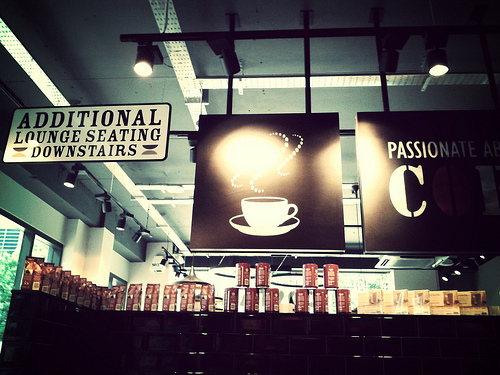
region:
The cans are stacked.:
[218, 252, 366, 321]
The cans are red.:
[219, 252, 351, 317]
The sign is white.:
[2, 104, 169, 168]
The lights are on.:
[51, 169, 78, 193]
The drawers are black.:
[12, 265, 490, 374]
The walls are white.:
[58, 204, 169, 291]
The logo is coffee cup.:
[197, 112, 334, 260]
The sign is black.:
[360, 109, 485, 262]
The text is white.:
[355, 115, 470, 237]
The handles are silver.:
[335, 308, 395, 365]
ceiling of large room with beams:
[25, 10, 466, 95]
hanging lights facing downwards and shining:
[115, 30, 461, 85]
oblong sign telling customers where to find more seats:
[2, 85, 172, 175]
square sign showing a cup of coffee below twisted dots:
[182, 60, 352, 277]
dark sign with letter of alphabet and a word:
[355, 80, 491, 260]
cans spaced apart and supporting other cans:
[217, 260, 349, 311]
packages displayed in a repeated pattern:
[357, 281, 487, 316]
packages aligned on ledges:
[15, 242, 216, 313]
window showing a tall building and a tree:
[1, 215, 26, 317]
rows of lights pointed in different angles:
[63, 175, 183, 275]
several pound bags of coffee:
[6, 230, 226, 316]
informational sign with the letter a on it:
[0, 80, 188, 187]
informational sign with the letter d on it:
[0, 86, 199, 173]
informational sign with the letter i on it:
[0, 88, 196, 182]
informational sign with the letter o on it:
[0, 79, 192, 176]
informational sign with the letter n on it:
[0, 81, 206, 196]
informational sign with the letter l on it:
[1, 86, 187, 179]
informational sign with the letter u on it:
[3, 77, 188, 176]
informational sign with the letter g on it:
[0, 78, 182, 220]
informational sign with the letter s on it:
[7, 51, 192, 175]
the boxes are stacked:
[219, 261, 281, 312]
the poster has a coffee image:
[191, 112, 338, 247]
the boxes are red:
[225, 262, 348, 309]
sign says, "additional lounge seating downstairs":
[3, 107, 172, 162]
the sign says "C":
[366, 110, 488, 252]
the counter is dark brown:
[1, 288, 499, 371]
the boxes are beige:
[358, 288, 488, 314]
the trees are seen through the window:
[0, 210, 25, 336]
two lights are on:
[133, 60, 449, 76]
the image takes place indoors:
[0, 0, 499, 372]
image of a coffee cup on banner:
[224, 187, 313, 241]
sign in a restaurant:
[0, 98, 178, 172]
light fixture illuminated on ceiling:
[124, 38, 173, 79]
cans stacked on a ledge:
[214, 254, 292, 319]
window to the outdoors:
[0, 219, 21, 293]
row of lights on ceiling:
[65, 162, 162, 252]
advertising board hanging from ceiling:
[349, 101, 494, 263]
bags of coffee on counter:
[20, 253, 125, 320]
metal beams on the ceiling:
[3, 37, 65, 102]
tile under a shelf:
[104, 316, 488, 361]